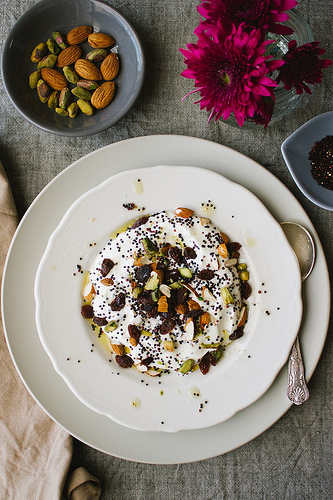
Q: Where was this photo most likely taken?
A: A restaurant.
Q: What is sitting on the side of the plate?
A: A spoon.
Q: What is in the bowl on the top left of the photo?
A: Nuts.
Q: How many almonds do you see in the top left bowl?
A: 7.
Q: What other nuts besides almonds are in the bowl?
A: Pistachios.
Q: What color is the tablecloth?
A: Grey.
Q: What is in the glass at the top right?
A: Flowers.